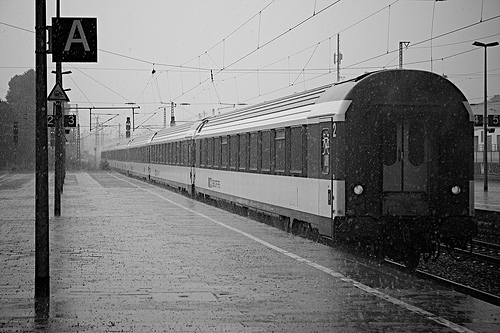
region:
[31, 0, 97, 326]
pole with letter A suspeded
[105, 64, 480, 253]
train on train tracks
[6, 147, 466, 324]
train platform made with brick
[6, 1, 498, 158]
electrical wiring above train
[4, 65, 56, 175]
trees in the background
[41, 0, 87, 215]
pole with numbers 2 and 3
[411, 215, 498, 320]
black metal train tracks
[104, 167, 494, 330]
white painted line on platform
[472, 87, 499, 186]
buildings behind train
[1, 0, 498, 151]
grey overcast sky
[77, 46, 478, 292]
train pulled along platform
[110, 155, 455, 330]
white strip near platform edge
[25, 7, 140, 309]
sign with letter on pole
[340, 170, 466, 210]
round headlights on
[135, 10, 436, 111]
wires along top of train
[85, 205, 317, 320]
platform composed of bricks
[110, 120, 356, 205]
light stripe below passenger windows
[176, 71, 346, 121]
ridged lines on train roof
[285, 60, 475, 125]
dome shape of train roof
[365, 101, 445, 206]
double doors with oval windows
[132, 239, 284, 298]
rain splashing on the platform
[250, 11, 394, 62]
numerous electrical grids over head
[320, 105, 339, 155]
large white number on side of train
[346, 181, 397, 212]
white light on front of train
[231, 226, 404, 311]
large solid white line on platform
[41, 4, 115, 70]
large black sign on post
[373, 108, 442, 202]
large white door on front of train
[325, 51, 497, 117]
domed top of train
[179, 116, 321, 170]
windows in train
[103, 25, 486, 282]
large passenger train at platform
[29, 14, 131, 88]
sign on a post with letter A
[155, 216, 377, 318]
train platform wet from rain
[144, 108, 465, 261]
passenger train moving through city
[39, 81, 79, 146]
signs on poles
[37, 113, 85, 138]
sign with numbers 2 and 3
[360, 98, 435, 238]
rear doors of passenger train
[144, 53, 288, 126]
overhead lines for powering train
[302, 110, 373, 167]
number 2 on train car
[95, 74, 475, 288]
train passing through in the rain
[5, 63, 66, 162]
trees in the distance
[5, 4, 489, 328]
the photo is black and white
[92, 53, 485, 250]
the train is long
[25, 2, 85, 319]
there are poles there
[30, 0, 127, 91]
the sign says A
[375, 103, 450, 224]
the train has doors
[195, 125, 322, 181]
the train has windows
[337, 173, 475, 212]
the train has lights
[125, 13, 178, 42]
the sky is clear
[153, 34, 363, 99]
there are wires everywhere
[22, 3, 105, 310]
there are many poles